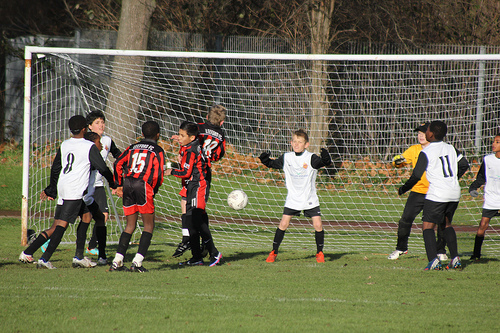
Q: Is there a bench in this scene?
A: No, there are no benches.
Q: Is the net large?
A: Yes, the net is large.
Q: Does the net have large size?
A: Yes, the net is large.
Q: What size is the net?
A: The net is large.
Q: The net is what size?
A: The net is large.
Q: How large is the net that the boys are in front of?
A: The net is large.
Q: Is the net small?
A: No, the net is large.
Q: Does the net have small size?
A: No, the net is large.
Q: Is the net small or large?
A: The net is large.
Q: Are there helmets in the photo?
A: No, there are no helmets.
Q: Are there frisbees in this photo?
A: No, there are no frisbees.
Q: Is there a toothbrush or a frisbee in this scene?
A: No, there are no frisbees or toothbrushes.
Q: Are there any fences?
A: Yes, there is a fence.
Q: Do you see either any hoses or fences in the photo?
A: Yes, there is a fence.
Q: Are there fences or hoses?
A: Yes, there is a fence.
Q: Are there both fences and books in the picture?
A: No, there is a fence but no books.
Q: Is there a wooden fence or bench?
A: Yes, there is a wood fence.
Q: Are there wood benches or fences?
A: Yes, there is a wood fence.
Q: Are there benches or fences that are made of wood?
A: Yes, the fence is made of wood.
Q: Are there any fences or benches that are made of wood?
A: Yes, the fence is made of wood.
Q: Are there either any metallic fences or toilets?
A: Yes, there is a metal fence.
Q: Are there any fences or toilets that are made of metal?
A: Yes, the fence is made of metal.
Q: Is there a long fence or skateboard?
A: Yes, there is a long fence.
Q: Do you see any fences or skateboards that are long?
A: Yes, the fence is long.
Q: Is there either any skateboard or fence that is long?
A: Yes, the fence is long.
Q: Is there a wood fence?
A: Yes, there is a fence that is made of wood.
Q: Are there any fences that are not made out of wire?
A: Yes, there is a fence that is made of wood.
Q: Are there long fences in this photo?
A: Yes, there is a long fence.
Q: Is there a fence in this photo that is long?
A: Yes, there is a fence that is long.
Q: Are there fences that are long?
A: Yes, there is a fence that is long.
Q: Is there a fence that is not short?
A: Yes, there is a long fence.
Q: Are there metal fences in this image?
A: Yes, there is a metal fence.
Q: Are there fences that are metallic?
A: Yes, there is a fence that is metallic.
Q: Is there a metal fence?
A: Yes, there is a fence that is made of metal.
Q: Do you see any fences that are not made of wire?
A: Yes, there is a fence that is made of metal.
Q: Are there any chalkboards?
A: No, there are no chalkboards.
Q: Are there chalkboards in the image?
A: No, there are no chalkboards.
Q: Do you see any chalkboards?
A: No, there are no chalkboards.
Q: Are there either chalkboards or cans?
A: No, there are no chalkboards or cans.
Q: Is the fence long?
A: Yes, the fence is long.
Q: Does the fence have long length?
A: Yes, the fence is long.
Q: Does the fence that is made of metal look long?
A: Yes, the fence is long.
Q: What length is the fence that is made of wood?
A: The fence is long.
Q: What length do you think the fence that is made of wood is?
A: The fence is long.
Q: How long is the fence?
A: The fence is long.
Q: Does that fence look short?
A: No, the fence is long.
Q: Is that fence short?
A: No, the fence is long.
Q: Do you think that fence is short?
A: No, the fence is long.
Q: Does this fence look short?
A: No, the fence is long.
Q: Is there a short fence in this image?
A: No, there is a fence but it is long.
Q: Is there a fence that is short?
A: No, there is a fence but it is long.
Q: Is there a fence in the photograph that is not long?
A: No, there is a fence but it is long.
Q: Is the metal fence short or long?
A: The fence is long.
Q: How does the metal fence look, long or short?
A: The fence is long.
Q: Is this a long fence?
A: Yes, this is a long fence.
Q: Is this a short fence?
A: No, this is a long fence.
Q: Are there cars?
A: No, there are no cars.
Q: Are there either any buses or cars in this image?
A: No, there are no cars or buses.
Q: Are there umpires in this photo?
A: No, there are no umpires.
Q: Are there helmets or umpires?
A: No, there are no umpires or helmets.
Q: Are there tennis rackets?
A: No, there are no tennis rackets.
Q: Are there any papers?
A: No, there are no papers.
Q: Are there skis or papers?
A: No, there are no papers or skis.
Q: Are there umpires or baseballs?
A: No, there are no baseballs or umpires.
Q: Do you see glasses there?
A: No, there are no glasses.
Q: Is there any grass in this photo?
A: Yes, there is grass.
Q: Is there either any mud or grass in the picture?
A: Yes, there is grass.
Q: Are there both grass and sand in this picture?
A: No, there is grass but no sand.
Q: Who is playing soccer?
A: The boys are playing soccer.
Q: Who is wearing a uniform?
A: The boys are wearing a uniform.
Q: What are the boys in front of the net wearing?
A: The boys are wearing a uniform.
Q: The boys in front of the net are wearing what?
A: The boys are wearing a uniform.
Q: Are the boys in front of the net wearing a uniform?
A: Yes, the boys are wearing a uniform.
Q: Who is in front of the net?
A: The boys are in front of the net.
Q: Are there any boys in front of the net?
A: Yes, there are boys in front of the net.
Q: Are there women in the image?
A: No, there are no women.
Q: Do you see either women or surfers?
A: No, there are no women or surfers.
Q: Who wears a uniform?
A: The boys wear a uniform.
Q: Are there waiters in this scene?
A: No, there are no waiters.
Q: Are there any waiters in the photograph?
A: No, there are no waiters.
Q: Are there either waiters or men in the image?
A: No, there are no waiters or men.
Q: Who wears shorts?
A: The boy wears shorts.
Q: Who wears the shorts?
A: The boy wears shorts.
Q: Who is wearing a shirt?
A: The boy is wearing a shirt.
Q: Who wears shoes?
A: The boy wears shoes.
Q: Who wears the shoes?
A: The boy wears shoes.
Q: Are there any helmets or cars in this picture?
A: No, there are no cars or helmets.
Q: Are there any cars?
A: No, there are no cars.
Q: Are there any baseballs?
A: No, there are no baseballs.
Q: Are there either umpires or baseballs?
A: No, there are no baseballs or umpires.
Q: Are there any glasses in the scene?
A: No, there are no glasses.